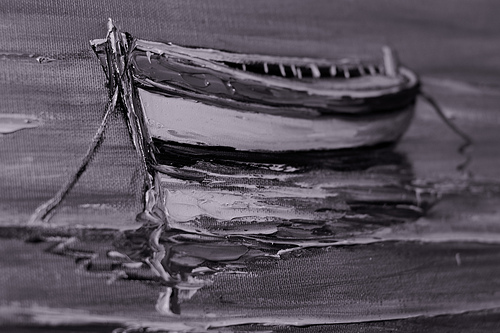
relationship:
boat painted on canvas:
[84, 15, 428, 180] [1, 0, 498, 331]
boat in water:
[84, 15, 428, 180] [73, 165, 436, 297]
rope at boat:
[417, 84, 474, 143] [84, 15, 428, 180]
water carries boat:
[46, 158, 497, 319] [69, 22, 436, 200]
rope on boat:
[28, 84, 123, 226] [84, 15, 428, 180]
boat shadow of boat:
[131, 150, 428, 318] [97, 15, 455, 177]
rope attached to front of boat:
[28, 84, 123, 226] [84, 15, 428, 180]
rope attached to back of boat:
[28, 84, 123, 226] [84, 15, 428, 180]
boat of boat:
[87, 15, 422, 154] [94, 27, 418, 180]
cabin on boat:
[217, 52, 382, 77] [84, 15, 428, 180]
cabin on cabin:
[218, 60, 382, 80] [165, 39, 373, 131]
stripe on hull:
[139, 85, 416, 150] [116, 59, 401, 160]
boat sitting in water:
[87, 15, 422, 154] [0, 1, 499, 331]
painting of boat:
[185, 97, 496, 331] [87, 15, 422, 154]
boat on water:
[87, 15, 422, 154] [26, 12, 462, 315]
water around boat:
[46, 158, 497, 319] [94, 27, 418, 180]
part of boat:
[104, 17, 161, 174] [84, 15, 428, 180]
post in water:
[89, 17, 159, 192] [310, 184, 389, 212]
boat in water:
[87, 15, 422, 154] [144, 163, 356, 262]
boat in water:
[87, 15, 422, 154] [0, 1, 499, 331]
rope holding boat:
[417, 84, 474, 143] [94, 27, 418, 180]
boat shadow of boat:
[144, 145, 429, 314] [94, 27, 418, 180]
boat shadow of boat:
[131, 150, 428, 318] [78, 22, 425, 163]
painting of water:
[0, 2, 500, 333] [171, 191, 196, 247]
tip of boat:
[105, 19, 119, 35] [84, 15, 428, 180]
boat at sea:
[87, 15, 422, 154] [2, 1, 497, 331]